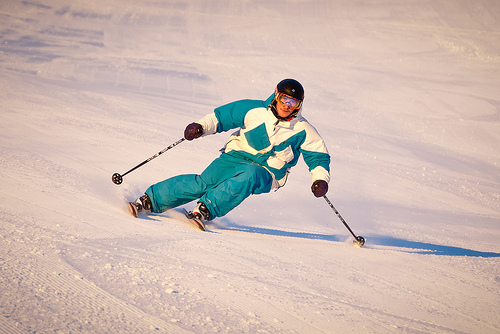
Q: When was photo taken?
A: Daytime.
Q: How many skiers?
A: 1.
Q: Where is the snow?
A: Ground.